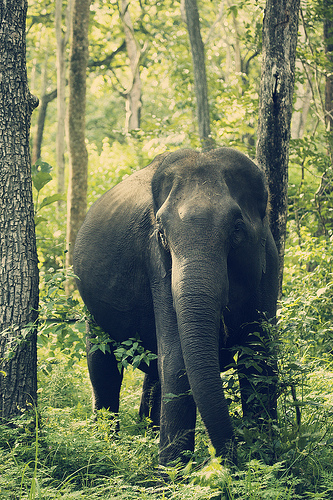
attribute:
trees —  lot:
[50, 9, 268, 136]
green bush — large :
[3, 455, 153, 499]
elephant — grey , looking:
[73, 142, 281, 468]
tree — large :
[264, 4, 294, 291]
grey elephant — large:
[66, 133, 304, 475]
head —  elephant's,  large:
[143, 143, 276, 303]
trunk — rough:
[1, 128, 44, 246]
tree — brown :
[1, 206, 34, 320]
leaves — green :
[131, 30, 226, 98]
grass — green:
[20, 396, 41, 498]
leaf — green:
[74, 319, 87, 334]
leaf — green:
[84, 344, 98, 355]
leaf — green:
[98, 342, 107, 354]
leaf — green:
[86, 336, 100, 343]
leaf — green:
[120, 339, 133, 346]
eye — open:
[155, 224, 165, 237]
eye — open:
[233, 220, 242, 227]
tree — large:
[1, 0, 38, 449]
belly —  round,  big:
[72, 180, 151, 348]